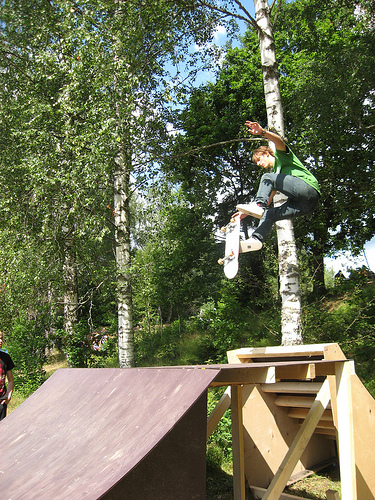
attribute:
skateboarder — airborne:
[212, 118, 325, 281]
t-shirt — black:
[1, 341, 18, 399]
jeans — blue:
[252, 174, 310, 237]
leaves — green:
[95, 60, 115, 85]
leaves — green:
[91, 131, 110, 157]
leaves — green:
[49, 103, 73, 135]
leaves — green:
[50, 149, 68, 178]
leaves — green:
[62, 202, 94, 223]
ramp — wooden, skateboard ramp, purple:
[6, 362, 220, 497]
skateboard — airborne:
[218, 213, 241, 281]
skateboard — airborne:
[221, 207, 243, 279]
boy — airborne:
[232, 116, 325, 254]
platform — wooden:
[144, 358, 348, 383]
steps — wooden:
[262, 380, 337, 441]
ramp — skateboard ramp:
[226, 342, 373, 498]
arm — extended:
[243, 119, 285, 151]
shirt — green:
[274, 142, 321, 193]